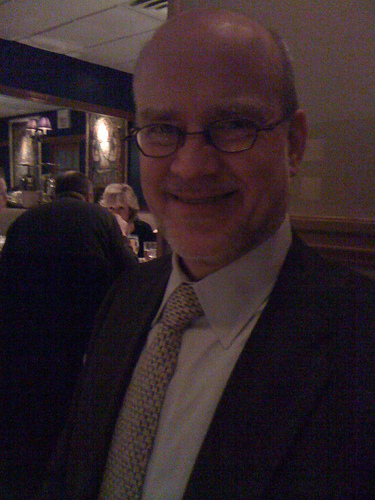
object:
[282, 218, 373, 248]
trim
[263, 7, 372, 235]
wall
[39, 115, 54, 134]
light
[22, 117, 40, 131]
light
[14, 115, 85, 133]
wall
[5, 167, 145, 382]
man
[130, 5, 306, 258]
head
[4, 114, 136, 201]
wall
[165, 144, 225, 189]
nose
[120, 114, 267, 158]
glasses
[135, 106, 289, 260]
face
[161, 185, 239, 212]
smiling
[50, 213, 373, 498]
suit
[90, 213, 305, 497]
shirt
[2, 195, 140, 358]
shirt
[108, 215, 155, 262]
shirt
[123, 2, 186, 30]
vent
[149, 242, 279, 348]
collar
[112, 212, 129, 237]
napkin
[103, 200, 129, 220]
face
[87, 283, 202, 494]
tie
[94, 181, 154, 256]
woman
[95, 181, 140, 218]
hair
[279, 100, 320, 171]
ear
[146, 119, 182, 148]
eye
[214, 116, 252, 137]
eye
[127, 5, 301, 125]
balding head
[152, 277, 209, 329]
knot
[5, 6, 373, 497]
restaurant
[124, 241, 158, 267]
table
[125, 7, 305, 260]
man's face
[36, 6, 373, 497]
man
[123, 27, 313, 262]
man's